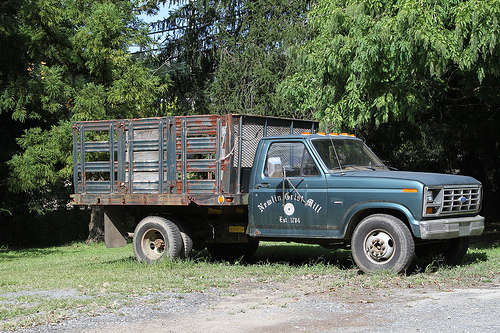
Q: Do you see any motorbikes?
A: No, there are no motorbikes.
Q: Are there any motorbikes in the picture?
A: No, there are no motorbikes.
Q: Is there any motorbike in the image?
A: No, there are no motorcycles.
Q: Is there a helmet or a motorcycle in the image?
A: No, there are no motorcycles or helmets.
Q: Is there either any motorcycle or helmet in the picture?
A: No, there are no motorcycles or helmets.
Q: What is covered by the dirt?
A: The ground is covered by the dirt.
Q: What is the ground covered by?
A: The ground is covered by the dirt.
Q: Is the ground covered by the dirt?
A: Yes, the ground is covered by the dirt.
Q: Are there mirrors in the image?
A: Yes, there is a mirror.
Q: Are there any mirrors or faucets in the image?
A: Yes, there is a mirror.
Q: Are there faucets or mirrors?
A: Yes, there is a mirror.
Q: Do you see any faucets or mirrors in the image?
A: Yes, there is a mirror.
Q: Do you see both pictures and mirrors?
A: No, there is a mirror but no pictures.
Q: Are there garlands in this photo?
A: No, there are no garlands.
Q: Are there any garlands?
A: No, there are no garlands.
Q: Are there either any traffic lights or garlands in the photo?
A: No, there are no garlands or traffic lights.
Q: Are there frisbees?
A: No, there are no frisbees.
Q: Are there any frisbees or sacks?
A: No, there are no frisbees or sacks.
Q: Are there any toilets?
A: No, there are no toilets.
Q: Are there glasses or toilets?
A: No, there are no toilets or glasses.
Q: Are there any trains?
A: No, there are no trains.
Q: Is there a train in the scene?
A: No, there are no trains.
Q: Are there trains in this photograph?
A: No, there are no trains.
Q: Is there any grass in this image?
A: Yes, there is grass.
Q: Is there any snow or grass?
A: Yes, there is grass.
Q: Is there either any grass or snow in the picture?
A: Yes, there is grass.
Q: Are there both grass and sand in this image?
A: No, there is grass but no sand.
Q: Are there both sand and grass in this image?
A: No, there is grass but no sand.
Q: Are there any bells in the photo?
A: No, there are no bells.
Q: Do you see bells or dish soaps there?
A: No, there are no bells or dish soaps.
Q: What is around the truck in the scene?
A: The grass is around the truck.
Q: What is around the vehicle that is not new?
A: The grass is around the truck.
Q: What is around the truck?
A: The grass is around the truck.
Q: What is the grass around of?
A: The grass is around the truck.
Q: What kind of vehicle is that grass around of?
A: The grass is around the truck.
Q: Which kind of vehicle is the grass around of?
A: The grass is around the truck.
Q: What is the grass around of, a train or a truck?
A: The grass is around a truck.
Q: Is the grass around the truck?
A: Yes, the grass is around the truck.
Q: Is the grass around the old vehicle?
A: Yes, the grass is around the truck.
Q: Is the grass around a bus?
A: No, the grass is around the truck.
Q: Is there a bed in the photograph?
A: Yes, there is a bed.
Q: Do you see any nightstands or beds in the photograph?
A: Yes, there is a bed.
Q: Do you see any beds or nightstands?
A: Yes, there is a bed.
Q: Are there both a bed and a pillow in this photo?
A: No, there is a bed but no pillows.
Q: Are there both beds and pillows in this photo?
A: No, there is a bed but no pillows.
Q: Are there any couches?
A: No, there are no couches.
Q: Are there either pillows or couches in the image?
A: No, there are no couches or pillows.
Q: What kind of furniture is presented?
A: The furniture is a bed.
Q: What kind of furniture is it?
A: The piece of furniture is a bed.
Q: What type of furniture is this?
A: This is a bed.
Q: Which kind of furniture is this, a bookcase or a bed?
A: This is a bed.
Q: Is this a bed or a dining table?
A: This is a bed.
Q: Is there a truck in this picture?
A: Yes, there is a truck.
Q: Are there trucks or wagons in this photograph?
A: Yes, there is a truck.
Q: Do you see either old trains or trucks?
A: Yes, there is an old truck.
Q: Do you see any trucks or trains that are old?
A: Yes, the truck is old.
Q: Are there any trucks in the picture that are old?
A: Yes, there is an old truck.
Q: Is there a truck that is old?
A: Yes, there is a truck that is old.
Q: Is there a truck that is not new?
A: Yes, there is a old truck.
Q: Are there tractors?
A: No, there are no tractors.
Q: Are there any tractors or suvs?
A: No, there are no tractors or suvs.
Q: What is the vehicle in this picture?
A: The vehicle is a truck.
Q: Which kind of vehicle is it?
A: The vehicle is a truck.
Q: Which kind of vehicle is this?
A: That is a truck.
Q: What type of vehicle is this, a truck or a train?
A: That is a truck.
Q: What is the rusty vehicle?
A: The vehicle is a truck.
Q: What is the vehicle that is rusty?
A: The vehicle is a truck.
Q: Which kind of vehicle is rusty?
A: The vehicle is a truck.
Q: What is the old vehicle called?
A: The vehicle is a truck.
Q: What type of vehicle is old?
A: The vehicle is a truck.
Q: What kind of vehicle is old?
A: The vehicle is a truck.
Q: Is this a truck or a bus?
A: This is a truck.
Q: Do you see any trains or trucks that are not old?
A: No, there is a truck but it is old.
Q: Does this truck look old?
A: Yes, the truck is old.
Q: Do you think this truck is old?
A: Yes, the truck is old.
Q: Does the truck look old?
A: Yes, the truck is old.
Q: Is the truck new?
A: No, the truck is old.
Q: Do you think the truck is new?
A: No, the truck is old.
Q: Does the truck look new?
A: No, the truck is old.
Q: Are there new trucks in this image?
A: No, there is a truck but it is old.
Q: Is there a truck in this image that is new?
A: No, there is a truck but it is old.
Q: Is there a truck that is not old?
A: No, there is a truck but it is old.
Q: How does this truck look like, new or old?
A: The truck is old.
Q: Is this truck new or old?
A: The truck is old.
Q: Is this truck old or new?
A: The truck is old.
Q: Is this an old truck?
A: Yes, this is an old truck.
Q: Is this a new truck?
A: No, this is an old truck.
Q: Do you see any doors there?
A: Yes, there is a door.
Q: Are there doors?
A: Yes, there is a door.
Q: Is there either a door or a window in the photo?
A: Yes, there is a door.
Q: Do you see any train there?
A: No, there are no trains.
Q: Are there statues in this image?
A: No, there are no statues.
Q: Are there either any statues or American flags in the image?
A: No, there are no statues or American flags.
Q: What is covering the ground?
A: The dirt is covering the ground.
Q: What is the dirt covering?
A: The dirt is covering the ground.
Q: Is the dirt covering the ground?
A: Yes, the dirt is covering the ground.